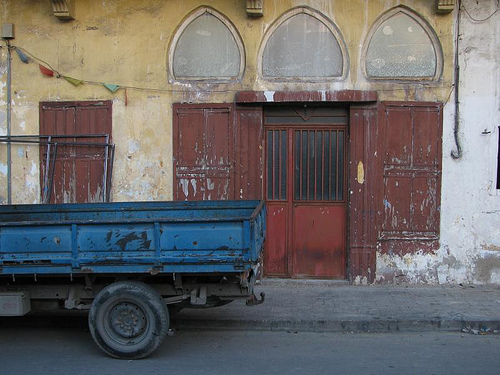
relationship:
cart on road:
[33, 202, 254, 323] [30, 316, 476, 367]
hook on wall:
[451, 0, 463, 159] [241, 51, 498, 218]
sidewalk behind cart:
[208, 294, 462, 370] [14, 212, 255, 354]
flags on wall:
[13, 31, 124, 101] [6, 2, 177, 199]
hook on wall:
[451, 61, 463, 163] [438, 9, 493, 265]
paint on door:
[250, 85, 375, 125] [247, 73, 383, 119]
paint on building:
[0, 0, 498, 293] [2, 0, 484, 290]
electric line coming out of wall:
[450, 0, 467, 163] [0, 0, 500, 286]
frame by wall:
[0, 131, 117, 201] [0, 0, 500, 286]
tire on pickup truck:
[86, 278, 169, 359] [2, 199, 270, 361]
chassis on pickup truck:
[0, 272, 269, 318] [2, 199, 270, 361]